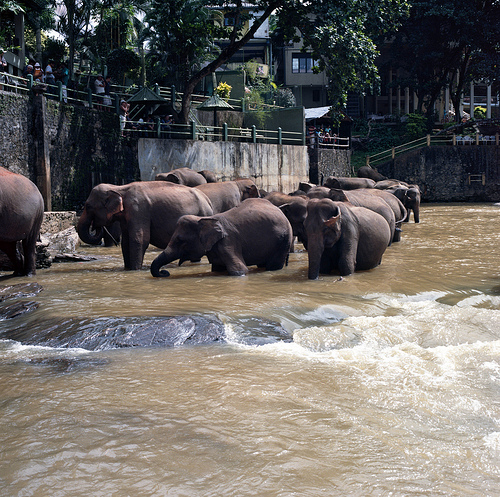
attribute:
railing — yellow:
[357, 128, 484, 167]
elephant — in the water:
[300, 195, 393, 284]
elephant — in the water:
[306, 194, 394, 279]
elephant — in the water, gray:
[150, 193, 295, 279]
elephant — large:
[293, 199, 388, 275]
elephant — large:
[73, 180, 207, 264]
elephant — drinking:
[374, 175, 424, 226]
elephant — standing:
[88, 189, 141, 239]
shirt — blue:
[59, 71, 89, 93]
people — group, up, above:
[44, 63, 108, 101]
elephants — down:
[86, 178, 174, 243]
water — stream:
[5, 275, 497, 484]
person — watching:
[311, 122, 341, 147]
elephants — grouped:
[61, 163, 433, 322]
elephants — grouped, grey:
[72, 160, 462, 299]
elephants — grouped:
[66, 150, 490, 308]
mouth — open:
[141, 245, 207, 273]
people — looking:
[26, 49, 158, 120]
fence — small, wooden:
[51, 73, 302, 154]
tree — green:
[314, 22, 423, 141]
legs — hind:
[9, 234, 53, 269]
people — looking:
[28, 57, 108, 109]